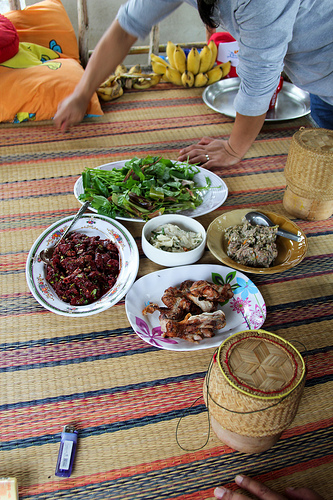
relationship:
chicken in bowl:
[141, 278, 232, 341] [121, 259, 271, 357]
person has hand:
[55, 1, 331, 175] [172, 131, 243, 173]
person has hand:
[55, 1, 331, 175] [49, 85, 101, 134]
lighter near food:
[35, 413, 109, 487] [147, 266, 237, 342]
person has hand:
[55, 1, 331, 175] [49, 98, 90, 133]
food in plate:
[44, 229, 119, 304] [230, 295, 260, 322]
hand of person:
[179, 136, 237, 165] [55, 1, 331, 175]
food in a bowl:
[220, 224, 283, 267] [200, 206, 315, 279]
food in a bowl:
[42, 227, 119, 302] [26, 210, 139, 317]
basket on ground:
[195, 305, 313, 471] [1, 70, 331, 497]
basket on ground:
[281, 127, 331, 224] [1, 70, 331, 497]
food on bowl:
[44, 229, 119, 304] [24, 211, 138, 318]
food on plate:
[78, 155, 210, 221] [71, 157, 230, 224]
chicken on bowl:
[162, 306, 226, 340] [124, 261, 265, 353]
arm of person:
[228, 0, 300, 159] [55, 1, 331, 175]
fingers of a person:
[176, 135, 222, 172] [55, 1, 331, 175]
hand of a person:
[174, 134, 236, 173] [55, 1, 331, 175]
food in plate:
[78, 155, 210, 221] [72, 157, 229, 223]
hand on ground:
[174, 134, 236, 173] [1, 70, 331, 497]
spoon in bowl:
[244, 209, 302, 243] [308, 205, 309, 275]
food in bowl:
[44, 229, 119, 304] [138, 203, 208, 263]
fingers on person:
[175, 132, 209, 170] [55, 1, 331, 175]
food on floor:
[78, 153, 211, 221] [0, 76, 330, 496]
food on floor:
[220, 219, 281, 266] [0, 76, 330, 496]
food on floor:
[44, 229, 119, 304] [0, 76, 330, 496]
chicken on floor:
[162, 306, 226, 340] [0, 76, 330, 496]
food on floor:
[147, 220, 203, 252] [0, 76, 330, 496]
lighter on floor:
[53, 422, 80, 480] [0, 76, 330, 496]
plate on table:
[77, 157, 229, 217] [0, 127, 29, 498]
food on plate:
[78, 155, 210, 221] [77, 157, 229, 217]